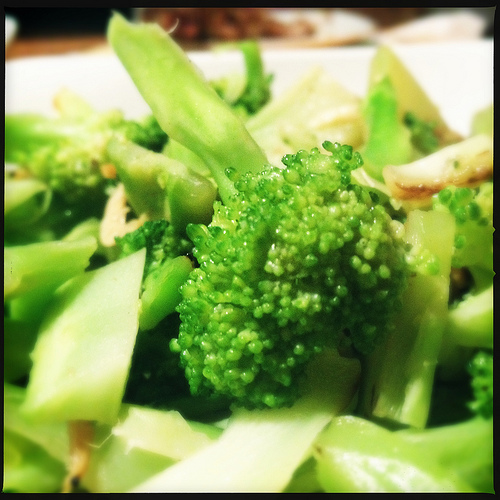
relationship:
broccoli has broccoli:
[103, 17, 271, 182] [103, 17, 271, 182]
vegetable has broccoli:
[387, 103, 495, 266] [103, 17, 271, 182]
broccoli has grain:
[103, 17, 271, 182] [222, 178, 377, 301]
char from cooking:
[403, 169, 490, 193] [23, 37, 500, 360]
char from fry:
[403, 169, 490, 193] [386, 138, 495, 211]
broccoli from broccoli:
[103, 17, 271, 182] [103, 17, 271, 182]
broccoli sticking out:
[103, 17, 271, 182] [107, 10, 178, 57]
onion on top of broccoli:
[382, 134, 497, 198] [106, 12, 415, 410]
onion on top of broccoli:
[382, 134, 497, 198] [213, 39, 270, 119]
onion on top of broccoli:
[382, 134, 497, 198] [467, 349, 494, 419]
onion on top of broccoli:
[382, 134, 497, 198] [0, 234, 97, 382]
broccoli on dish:
[158, 147, 430, 426] [0, 39, 493, 123]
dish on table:
[7, 46, 496, 498] [2, 7, 487, 491]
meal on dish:
[6, 10, 495, 491] [7, 46, 496, 498]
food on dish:
[19, 30, 482, 487] [0, 39, 493, 123]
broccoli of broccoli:
[103, 17, 271, 182] [169, 140, 491, 411]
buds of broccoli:
[169, 141, 407, 410] [110, 87, 450, 419]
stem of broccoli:
[21, 250, 149, 433] [24, 215, 179, 421]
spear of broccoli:
[19, 246, 155, 423] [19, 240, 154, 426]